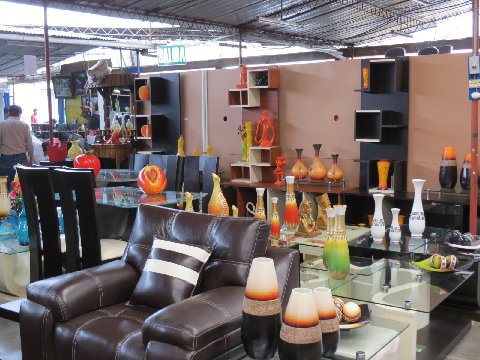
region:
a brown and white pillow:
[116, 231, 227, 350]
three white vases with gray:
[359, 160, 458, 266]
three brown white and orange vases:
[236, 238, 363, 358]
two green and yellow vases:
[306, 196, 370, 292]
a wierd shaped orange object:
[245, 107, 284, 155]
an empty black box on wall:
[335, 101, 398, 152]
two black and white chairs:
[1, 137, 139, 281]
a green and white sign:
[156, 38, 193, 73]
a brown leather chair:
[20, 198, 264, 359]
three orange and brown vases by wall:
[280, 132, 381, 186]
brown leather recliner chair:
[11, 203, 270, 358]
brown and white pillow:
[134, 236, 210, 300]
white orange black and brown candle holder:
[241, 255, 282, 358]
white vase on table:
[411, 177, 426, 242]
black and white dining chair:
[54, 165, 129, 272]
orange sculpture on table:
[137, 164, 167, 195]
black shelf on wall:
[353, 60, 410, 190]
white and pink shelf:
[226, 68, 280, 181]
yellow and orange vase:
[209, 172, 230, 217]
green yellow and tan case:
[331, 204, 350, 279]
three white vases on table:
[360, 173, 432, 243]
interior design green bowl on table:
[408, 247, 464, 276]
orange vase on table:
[126, 158, 174, 197]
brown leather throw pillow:
[124, 228, 221, 307]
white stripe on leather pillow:
[139, 231, 213, 288]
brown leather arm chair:
[15, 197, 304, 354]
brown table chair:
[4, 157, 108, 283]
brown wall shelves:
[340, 60, 424, 198]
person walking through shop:
[1, 95, 38, 200]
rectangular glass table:
[18, 178, 215, 215]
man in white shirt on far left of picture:
[6, 100, 34, 172]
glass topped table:
[45, 181, 206, 211]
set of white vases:
[361, 178, 430, 247]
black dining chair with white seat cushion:
[18, 168, 128, 292]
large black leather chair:
[15, 203, 301, 359]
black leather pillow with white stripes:
[133, 236, 211, 305]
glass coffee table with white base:
[325, 256, 475, 317]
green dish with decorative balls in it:
[414, 252, 462, 279]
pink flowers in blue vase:
[4, 177, 31, 251]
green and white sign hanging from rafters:
[150, 43, 189, 69]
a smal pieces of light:
[241, 256, 281, 341]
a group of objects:
[68, 122, 397, 356]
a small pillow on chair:
[129, 230, 208, 307]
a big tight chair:
[42, 197, 306, 346]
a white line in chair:
[129, 251, 194, 285]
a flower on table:
[129, 148, 177, 204]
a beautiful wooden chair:
[14, 147, 140, 299]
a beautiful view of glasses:
[348, 172, 446, 245]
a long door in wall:
[354, 71, 412, 237]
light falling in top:
[35, 13, 174, 71]